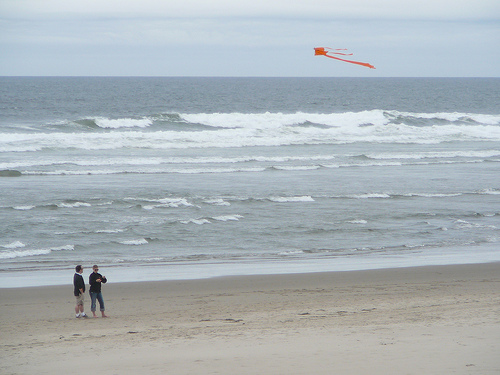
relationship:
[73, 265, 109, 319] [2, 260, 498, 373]
couple on beach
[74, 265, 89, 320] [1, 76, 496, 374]
man in beach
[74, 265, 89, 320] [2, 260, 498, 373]
man in beach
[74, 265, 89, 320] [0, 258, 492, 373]
man in sand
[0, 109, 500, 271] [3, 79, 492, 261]
wave in water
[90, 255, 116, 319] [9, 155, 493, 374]
people in beach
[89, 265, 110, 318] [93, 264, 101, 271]
people in hair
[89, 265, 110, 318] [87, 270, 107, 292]
people wearing sweater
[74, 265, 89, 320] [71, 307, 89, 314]
man wearing socks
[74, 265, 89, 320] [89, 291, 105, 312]
man wearing capris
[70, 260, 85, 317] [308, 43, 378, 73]
man flying kite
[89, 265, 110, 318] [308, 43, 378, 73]
people flying kite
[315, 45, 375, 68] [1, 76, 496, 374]
kite over beach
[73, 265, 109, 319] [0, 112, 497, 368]
couple at beach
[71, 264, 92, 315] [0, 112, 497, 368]
couple at beach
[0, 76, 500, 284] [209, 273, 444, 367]
water on shore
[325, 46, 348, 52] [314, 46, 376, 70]
streamer on kite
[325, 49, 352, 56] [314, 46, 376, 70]
streamer on kite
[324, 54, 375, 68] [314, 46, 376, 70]
streamer on kite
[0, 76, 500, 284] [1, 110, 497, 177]
water has waves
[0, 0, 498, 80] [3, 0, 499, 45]
sky has cloud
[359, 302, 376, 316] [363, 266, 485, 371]
track on sand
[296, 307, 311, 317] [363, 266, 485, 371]
track on sand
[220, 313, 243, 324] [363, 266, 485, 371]
track on sand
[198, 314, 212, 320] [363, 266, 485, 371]
track on sand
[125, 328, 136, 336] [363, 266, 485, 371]
track on sand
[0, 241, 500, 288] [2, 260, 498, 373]
water on beach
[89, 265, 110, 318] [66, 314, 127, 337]
people standing on sand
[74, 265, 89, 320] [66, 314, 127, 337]
man standing on sand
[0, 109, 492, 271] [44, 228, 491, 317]
wave coming into shore